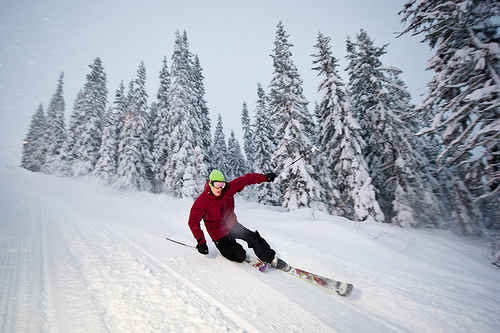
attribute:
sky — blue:
[5, 4, 425, 102]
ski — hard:
[262, 256, 370, 301]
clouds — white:
[61, 24, 141, 62]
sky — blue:
[36, 4, 361, 111]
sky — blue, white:
[1, 1, 441, 170]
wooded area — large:
[3, 0, 499, 231]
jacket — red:
[187, 172, 265, 244]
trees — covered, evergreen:
[268, 12, 405, 231]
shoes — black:
[243, 253, 289, 270]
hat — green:
[204, 167, 226, 184]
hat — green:
[209, 170, 226, 178]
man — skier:
[164, 151, 370, 321]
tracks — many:
[6, 167, 246, 332]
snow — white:
[2, 163, 499, 331]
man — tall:
[186, 168, 286, 270]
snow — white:
[334, 236, 411, 271]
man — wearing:
[171, 162, 380, 300]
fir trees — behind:
[245, 19, 328, 213]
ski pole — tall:
[162, 233, 202, 255]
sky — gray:
[12, 8, 166, 51]